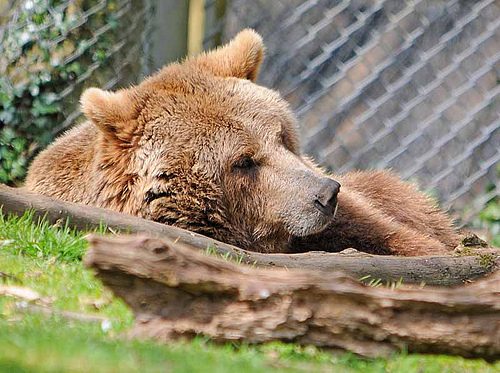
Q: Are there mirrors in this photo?
A: No, there are no mirrors.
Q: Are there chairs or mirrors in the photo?
A: No, there are no mirrors or chairs.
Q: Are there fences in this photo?
A: Yes, there is a fence.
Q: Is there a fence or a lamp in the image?
A: Yes, there is a fence.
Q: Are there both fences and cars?
A: No, there is a fence but no cars.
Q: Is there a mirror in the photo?
A: No, there are no mirrors.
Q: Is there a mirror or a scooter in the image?
A: No, there are no mirrors or scooters.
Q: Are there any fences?
A: Yes, there is a fence.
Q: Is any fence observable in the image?
A: Yes, there is a fence.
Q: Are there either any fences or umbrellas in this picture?
A: Yes, there is a fence.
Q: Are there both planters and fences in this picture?
A: No, there is a fence but no planters.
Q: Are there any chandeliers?
A: No, there are no chandeliers.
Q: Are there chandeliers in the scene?
A: No, there are no chandeliers.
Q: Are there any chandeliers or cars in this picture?
A: No, there are no chandeliers or cars.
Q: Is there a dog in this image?
A: No, there are no dogs.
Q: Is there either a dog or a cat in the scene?
A: No, there are no dogs or cats.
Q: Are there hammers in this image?
A: No, there are no hammers.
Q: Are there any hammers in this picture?
A: No, there are no hammers.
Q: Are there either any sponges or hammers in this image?
A: No, there are no hammers or sponges.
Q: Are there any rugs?
A: No, there are no rugs.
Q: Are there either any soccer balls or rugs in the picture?
A: No, there are no rugs or soccer balls.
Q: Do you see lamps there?
A: No, there are no lamps.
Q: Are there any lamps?
A: No, there are no lamps.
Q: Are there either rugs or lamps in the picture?
A: No, there are no lamps or rugs.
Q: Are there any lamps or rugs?
A: No, there are no lamps or rugs.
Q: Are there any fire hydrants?
A: No, there are no fire hydrants.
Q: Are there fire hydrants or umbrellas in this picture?
A: No, there are no fire hydrants or umbrellas.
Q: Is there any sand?
A: Yes, there is sand.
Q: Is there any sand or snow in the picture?
A: Yes, there is sand.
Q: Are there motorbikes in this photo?
A: No, there are no motorbikes.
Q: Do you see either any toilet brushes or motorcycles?
A: No, there are no motorcycles or toilet brushes.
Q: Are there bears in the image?
A: Yes, there is a bear.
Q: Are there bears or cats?
A: Yes, there is a bear.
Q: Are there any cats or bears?
A: Yes, there is a bear.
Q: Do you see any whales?
A: No, there are no whales.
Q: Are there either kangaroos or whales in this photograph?
A: No, there are no whales or kangaroos.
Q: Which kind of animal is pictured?
A: The animal is a bear.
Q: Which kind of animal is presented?
A: The animal is a bear.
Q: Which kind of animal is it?
A: The animal is a bear.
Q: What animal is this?
A: That is a bear.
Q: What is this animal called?
A: That is a bear.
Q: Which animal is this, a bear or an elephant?
A: That is a bear.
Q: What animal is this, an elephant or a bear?
A: That is a bear.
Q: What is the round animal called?
A: The animal is a bear.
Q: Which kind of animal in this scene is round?
A: The animal is a bear.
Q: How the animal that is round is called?
A: The animal is a bear.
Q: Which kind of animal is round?
A: The animal is a bear.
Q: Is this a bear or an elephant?
A: This is a bear.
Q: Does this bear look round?
A: Yes, the bear is round.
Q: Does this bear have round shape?
A: Yes, the bear is round.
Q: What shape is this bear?
A: The bear is round.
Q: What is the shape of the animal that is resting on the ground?
A: The bear is round.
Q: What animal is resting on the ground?
A: The bear is resting on the ground.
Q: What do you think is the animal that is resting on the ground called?
A: The animal is a bear.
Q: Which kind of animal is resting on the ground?
A: The animal is a bear.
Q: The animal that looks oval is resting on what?
A: The bear is resting on the ground.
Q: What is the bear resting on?
A: The bear is resting on the ground.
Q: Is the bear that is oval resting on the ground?
A: Yes, the bear is resting on the ground.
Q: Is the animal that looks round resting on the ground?
A: Yes, the bear is resting on the ground.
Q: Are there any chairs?
A: No, there are no chairs.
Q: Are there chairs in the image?
A: No, there are no chairs.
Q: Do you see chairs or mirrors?
A: No, there are no chairs or mirrors.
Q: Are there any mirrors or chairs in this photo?
A: No, there are no chairs or mirrors.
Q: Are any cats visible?
A: No, there are no cats.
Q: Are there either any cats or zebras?
A: No, there are no cats or zebras.